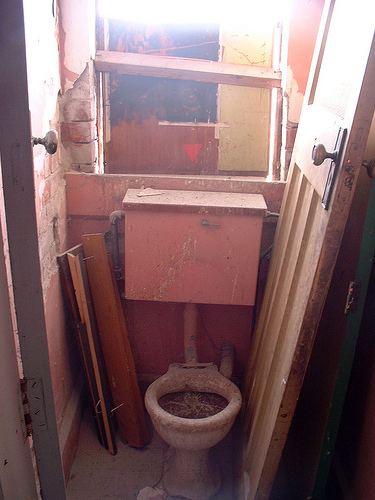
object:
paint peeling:
[102, 173, 144, 189]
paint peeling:
[38, 158, 63, 303]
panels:
[85, 234, 138, 448]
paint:
[67, 166, 114, 217]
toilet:
[146, 366, 234, 497]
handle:
[313, 133, 344, 189]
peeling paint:
[24, 0, 95, 413]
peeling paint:
[286, 3, 302, 165]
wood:
[52, 227, 152, 455]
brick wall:
[24, 9, 81, 498]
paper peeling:
[24, 11, 171, 138]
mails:
[91, 398, 123, 419]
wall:
[22, 0, 373, 491]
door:
[231, 0, 374, 477]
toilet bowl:
[146, 363, 241, 498]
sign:
[142, 363, 238, 498]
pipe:
[182, 303, 199, 364]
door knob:
[310, 141, 338, 165]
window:
[93, 10, 278, 187]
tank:
[125, 189, 259, 302]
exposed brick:
[35, 58, 105, 295]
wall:
[16, 9, 95, 339]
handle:
[203, 219, 224, 229]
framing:
[95, 49, 281, 89]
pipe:
[110, 203, 128, 286]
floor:
[85, 439, 136, 498]